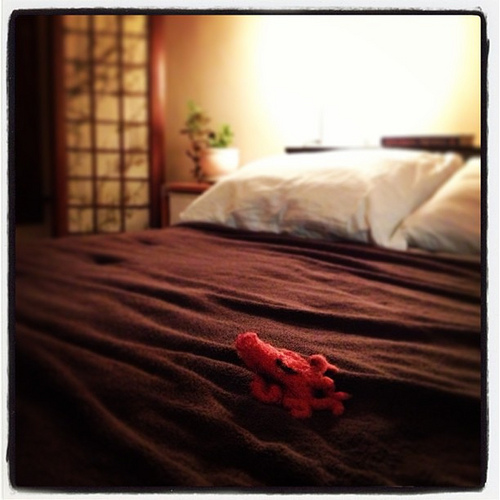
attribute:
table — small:
[149, 174, 215, 236]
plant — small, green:
[180, 106, 257, 179]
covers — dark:
[11, 220, 483, 492]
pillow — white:
[177, 149, 461, 250]